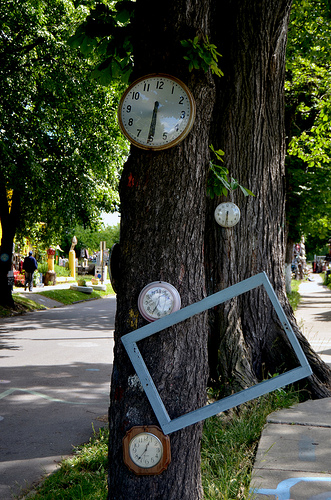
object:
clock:
[114, 69, 198, 153]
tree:
[110, 0, 221, 499]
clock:
[135, 275, 184, 327]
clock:
[119, 421, 174, 479]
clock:
[212, 199, 244, 229]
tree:
[199, 1, 330, 413]